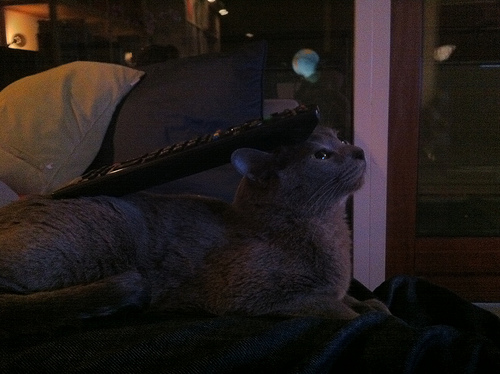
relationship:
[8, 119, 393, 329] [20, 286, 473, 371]
cat on top of blanket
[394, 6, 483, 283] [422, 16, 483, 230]
door has window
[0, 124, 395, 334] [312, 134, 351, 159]
cat has eyes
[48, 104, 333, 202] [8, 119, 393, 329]
remote control on top of cat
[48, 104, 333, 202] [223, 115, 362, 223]
remote control leaning on head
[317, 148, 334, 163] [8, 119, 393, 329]
eye of cat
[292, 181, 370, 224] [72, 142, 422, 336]
whiskers on cat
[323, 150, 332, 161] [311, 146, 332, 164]
light shining in eye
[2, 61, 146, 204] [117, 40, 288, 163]
pillow laying on pillow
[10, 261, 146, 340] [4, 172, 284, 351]
tail wrapped around body